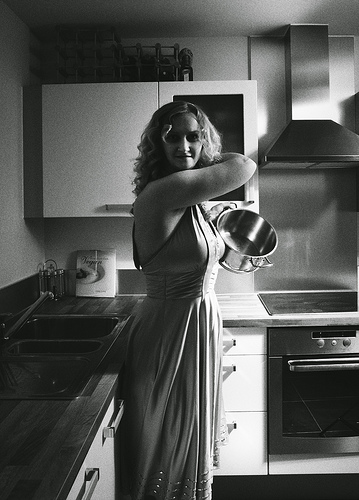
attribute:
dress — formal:
[127, 203, 227, 500]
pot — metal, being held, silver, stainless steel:
[216, 203, 279, 275]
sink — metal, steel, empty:
[0, 312, 131, 401]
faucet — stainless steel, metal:
[0, 291, 54, 344]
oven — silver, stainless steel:
[268, 326, 359, 455]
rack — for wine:
[29, 24, 179, 82]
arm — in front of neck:
[133, 152, 257, 210]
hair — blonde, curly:
[130, 100, 221, 214]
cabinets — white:
[40, 80, 258, 220]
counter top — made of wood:
[0, 289, 358, 498]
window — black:
[283, 353, 358, 439]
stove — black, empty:
[258, 291, 358, 316]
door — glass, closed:
[280, 353, 357, 437]